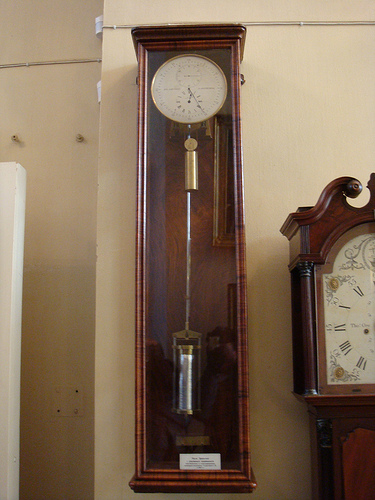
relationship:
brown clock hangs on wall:
[127, 21, 257, 497] [0, 0, 373, 497]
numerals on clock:
[327, 275, 374, 370] [279, 169, 375, 409]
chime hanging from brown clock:
[175, 127, 199, 420] [127, 21, 257, 497]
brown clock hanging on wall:
[129, 24, 259, 491] [94, 0, 374, 499]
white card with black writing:
[177, 451, 224, 470] [177, 450, 222, 471]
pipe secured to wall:
[9, 11, 372, 77] [0, 0, 373, 497]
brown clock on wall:
[127, 21, 257, 497] [94, 0, 374, 499]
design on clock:
[328, 353, 359, 380] [279, 169, 375, 409]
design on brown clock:
[325, 273, 351, 306] [127, 21, 257, 497]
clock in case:
[124, 17, 247, 490] [279, 165, 373, 498]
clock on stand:
[279, 169, 375, 409] [304, 405, 374, 499]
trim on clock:
[128, 23, 246, 47] [146, 49, 232, 128]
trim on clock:
[284, 173, 366, 235] [314, 227, 374, 395]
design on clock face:
[337, 238, 373, 272] [321, 233, 374, 385]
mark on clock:
[334, 364, 344, 378] [148, 50, 231, 123]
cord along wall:
[5, 18, 152, 65] [9, 16, 310, 486]